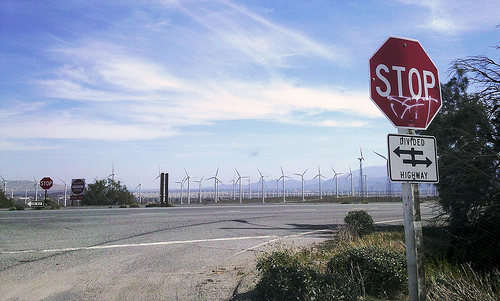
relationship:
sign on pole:
[388, 134, 439, 183] [397, 127, 420, 301]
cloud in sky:
[0, 63, 388, 145] [0, 2, 498, 190]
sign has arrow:
[388, 134, 439, 183] [394, 147, 434, 168]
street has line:
[1, 199, 443, 301] [1, 234, 280, 256]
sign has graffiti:
[368, 35, 443, 130] [387, 94, 439, 127]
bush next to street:
[72, 175, 143, 205] [1, 199, 443, 301]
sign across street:
[368, 35, 443, 130] [1, 199, 443, 301]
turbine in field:
[312, 164, 328, 200] [147, 197, 439, 205]